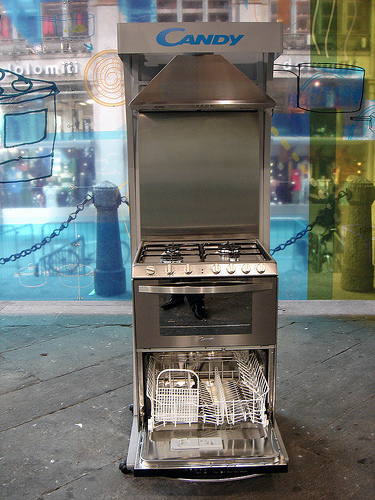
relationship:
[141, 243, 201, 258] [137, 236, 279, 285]
burner on stove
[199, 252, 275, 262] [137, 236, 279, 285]
burner on stove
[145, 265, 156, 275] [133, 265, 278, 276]
control on panel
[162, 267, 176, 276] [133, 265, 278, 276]
control on panel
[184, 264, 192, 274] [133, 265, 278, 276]
control on panel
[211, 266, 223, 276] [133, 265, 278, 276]
control on panel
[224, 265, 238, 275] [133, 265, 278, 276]
control on panel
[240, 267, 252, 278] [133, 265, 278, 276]
control on panel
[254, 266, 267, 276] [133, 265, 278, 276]
control on panel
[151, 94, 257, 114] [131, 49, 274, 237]
vent in hood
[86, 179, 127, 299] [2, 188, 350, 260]
post holding chain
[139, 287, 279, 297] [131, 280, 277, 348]
handle on door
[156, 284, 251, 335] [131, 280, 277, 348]
window on door